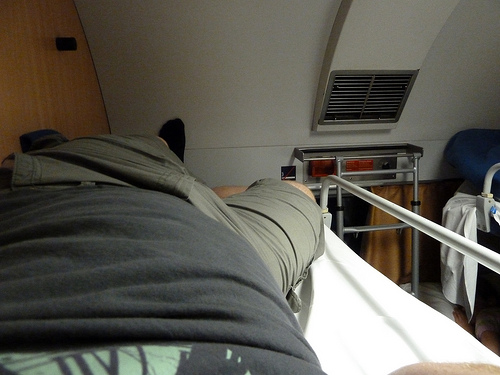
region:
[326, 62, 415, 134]
an open air vent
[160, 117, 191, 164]
a foot in a black sock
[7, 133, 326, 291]
a pair of shorts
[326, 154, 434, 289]
part of a silver ladder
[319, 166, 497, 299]
part of a silver rail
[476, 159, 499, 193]
part of a silver rail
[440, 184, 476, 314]
part of a white sheet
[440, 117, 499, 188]
part of a blue pillow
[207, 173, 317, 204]
part of a person's leg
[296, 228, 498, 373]
part of the bed mattress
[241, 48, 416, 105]
the wall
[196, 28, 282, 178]
the wall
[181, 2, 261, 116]
the wall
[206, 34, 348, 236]
the wall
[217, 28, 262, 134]
the wall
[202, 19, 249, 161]
the wall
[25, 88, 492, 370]
Man lying in cot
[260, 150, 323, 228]
Right knee is white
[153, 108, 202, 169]
Sock on left foot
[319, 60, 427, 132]
Vent in wall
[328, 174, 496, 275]
Handle bar beside bed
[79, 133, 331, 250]
Shorts are dark green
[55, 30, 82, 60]
Black circular object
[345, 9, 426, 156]
Arch on wall is white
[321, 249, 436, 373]
Bed sheets are bright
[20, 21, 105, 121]
Brown wooden panel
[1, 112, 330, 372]
person on stretcher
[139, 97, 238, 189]
person wearing socks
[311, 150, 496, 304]
metal bar of stretcher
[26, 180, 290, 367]
person wearing dark grey shirt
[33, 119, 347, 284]
person wearing drab shorts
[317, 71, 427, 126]
air vent on wall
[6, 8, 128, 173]
wooden paneling on wall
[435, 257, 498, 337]
another person laying down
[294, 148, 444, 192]
machinery on wall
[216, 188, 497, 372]
bed covered in white linen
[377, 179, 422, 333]
a side rail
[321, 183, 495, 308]
the side rail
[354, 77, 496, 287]
the side rail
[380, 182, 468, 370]
the side rail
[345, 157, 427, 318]
the side rail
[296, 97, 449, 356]
the side rail